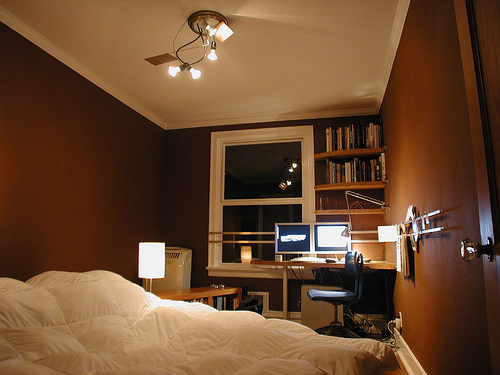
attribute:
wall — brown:
[2, 1, 493, 373]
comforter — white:
[1, 267, 401, 374]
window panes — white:
[206, 124, 318, 225]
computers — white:
[270, 218, 355, 253]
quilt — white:
[0, 292, 387, 373]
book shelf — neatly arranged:
[313, 117, 391, 206]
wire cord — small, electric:
[380, 314, 402, 357]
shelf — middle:
[320, 178, 380, 191]